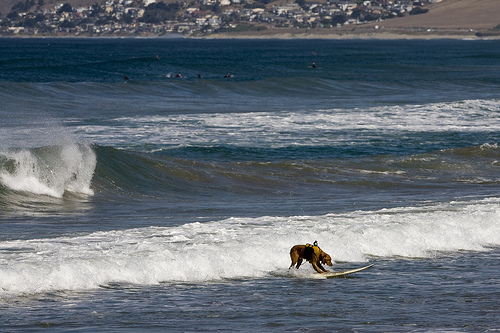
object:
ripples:
[339, 173, 498, 190]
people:
[176, 73, 184, 78]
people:
[122, 75, 129, 84]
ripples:
[50, 288, 125, 323]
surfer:
[312, 61, 317, 68]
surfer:
[223, 73, 231, 79]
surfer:
[197, 73, 203, 79]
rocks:
[460, 36, 485, 42]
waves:
[0, 143, 71, 208]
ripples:
[279, 323, 392, 332]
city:
[0, 0, 437, 37]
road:
[343, 0, 500, 38]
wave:
[0, 140, 103, 198]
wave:
[0, 235, 56, 299]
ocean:
[0, 38, 500, 333]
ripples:
[335, 310, 487, 330]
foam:
[0, 200, 500, 308]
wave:
[335, 195, 499, 266]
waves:
[146, 219, 246, 287]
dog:
[287, 243, 332, 273]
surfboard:
[273, 263, 375, 281]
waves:
[355, 231, 421, 262]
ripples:
[319, 166, 371, 177]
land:
[217, 0, 498, 38]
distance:
[1, 0, 499, 38]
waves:
[202, 110, 297, 132]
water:
[0, 34, 500, 333]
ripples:
[126, 202, 323, 213]